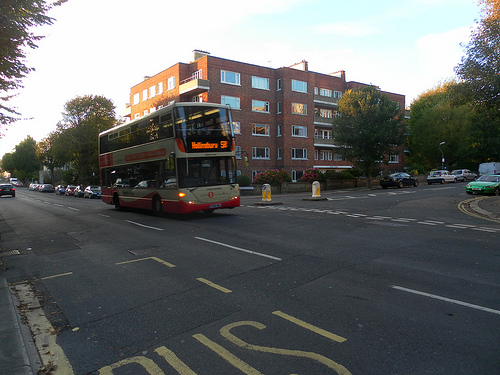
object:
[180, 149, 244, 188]
windshield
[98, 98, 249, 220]
bus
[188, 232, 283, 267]
line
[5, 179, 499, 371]
street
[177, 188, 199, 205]
headlights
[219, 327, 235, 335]
paint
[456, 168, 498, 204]
car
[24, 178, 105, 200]
cars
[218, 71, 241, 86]
windows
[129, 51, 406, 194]
building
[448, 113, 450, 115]
leaves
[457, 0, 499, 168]
trees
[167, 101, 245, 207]
front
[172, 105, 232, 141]
window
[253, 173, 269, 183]
flowers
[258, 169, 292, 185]
bush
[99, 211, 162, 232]
lines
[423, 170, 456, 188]
car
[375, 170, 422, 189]
car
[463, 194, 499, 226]
corner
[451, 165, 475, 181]
sedan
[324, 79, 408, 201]
tree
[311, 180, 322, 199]
trash can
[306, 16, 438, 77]
clouds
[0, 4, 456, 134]
sky